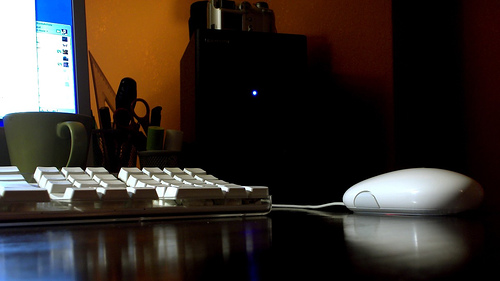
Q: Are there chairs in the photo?
A: No, there are no chairs.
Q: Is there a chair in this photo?
A: No, there are no chairs.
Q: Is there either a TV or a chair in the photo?
A: No, there are no chairs or televisions.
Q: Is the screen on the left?
A: Yes, the screen is on the left of the image.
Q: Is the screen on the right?
A: No, the screen is on the left of the image.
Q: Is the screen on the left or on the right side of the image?
A: The screen is on the left of the image.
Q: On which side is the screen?
A: The screen is on the left of the image.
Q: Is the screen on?
A: Yes, the screen is on.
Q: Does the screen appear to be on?
A: Yes, the screen is on.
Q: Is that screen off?
A: No, the screen is on.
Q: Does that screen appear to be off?
A: No, the screen is on.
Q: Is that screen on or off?
A: The screen is on.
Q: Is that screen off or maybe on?
A: The screen is on.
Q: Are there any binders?
A: No, there are no binders.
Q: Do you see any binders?
A: No, there are no binders.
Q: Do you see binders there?
A: No, there are no binders.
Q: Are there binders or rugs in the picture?
A: No, there are no binders or rugs.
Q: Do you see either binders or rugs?
A: No, there are no binders or rugs.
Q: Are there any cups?
A: Yes, there is a cup.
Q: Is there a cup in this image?
A: Yes, there is a cup.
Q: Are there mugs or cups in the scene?
A: Yes, there is a cup.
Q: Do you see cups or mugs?
A: Yes, there is a cup.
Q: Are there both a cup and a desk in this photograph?
A: Yes, there are both a cup and a desk.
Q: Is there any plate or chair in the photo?
A: No, there are no chairs or plates.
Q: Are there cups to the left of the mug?
A: No, the cup is to the right of the mug.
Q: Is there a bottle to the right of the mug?
A: No, there is a cup to the right of the mug.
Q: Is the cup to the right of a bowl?
A: No, the cup is to the right of the mug.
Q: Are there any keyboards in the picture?
A: Yes, there is a keyboard.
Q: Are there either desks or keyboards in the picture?
A: Yes, there is a keyboard.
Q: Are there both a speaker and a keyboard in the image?
A: No, there is a keyboard but no speakers.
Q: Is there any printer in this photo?
A: No, there are no printers.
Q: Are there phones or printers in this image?
A: No, there are no printers or phones.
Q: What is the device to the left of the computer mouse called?
A: The device is a keyboard.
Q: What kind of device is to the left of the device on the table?
A: The device is a keyboard.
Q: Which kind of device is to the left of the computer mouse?
A: The device is a keyboard.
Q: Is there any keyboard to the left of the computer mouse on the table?
A: Yes, there is a keyboard to the left of the mouse.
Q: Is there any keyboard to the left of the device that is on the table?
A: Yes, there is a keyboard to the left of the mouse.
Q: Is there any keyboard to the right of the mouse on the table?
A: No, the keyboard is to the left of the mouse.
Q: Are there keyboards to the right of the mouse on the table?
A: No, the keyboard is to the left of the mouse.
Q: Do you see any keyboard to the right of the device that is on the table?
A: No, the keyboard is to the left of the mouse.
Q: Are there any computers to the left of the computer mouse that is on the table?
A: No, there is a keyboard to the left of the mouse.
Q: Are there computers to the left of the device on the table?
A: No, there is a keyboard to the left of the mouse.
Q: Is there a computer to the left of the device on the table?
A: No, there is a keyboard to the left of the mouse.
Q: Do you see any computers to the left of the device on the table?
A: No, there is a keyboard to the left of the mouse.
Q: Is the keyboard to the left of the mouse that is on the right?
A: Yes, the keyboard is to the left of the mouse.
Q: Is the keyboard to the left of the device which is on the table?
A: Yes, the keyboard is to the left of the mouse.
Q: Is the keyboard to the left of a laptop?
A: No, the keyboard is to the left of the mouse.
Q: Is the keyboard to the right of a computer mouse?
A: No, the keyboard is to the left of a computer mouse.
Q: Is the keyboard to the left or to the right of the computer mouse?
A: The keyboard is to the left of the computer mouse.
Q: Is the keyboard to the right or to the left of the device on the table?
A: The keyboard is to the left of the computer mouse.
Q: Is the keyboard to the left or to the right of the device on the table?
A: The keyboard is to the left of the computer mouse.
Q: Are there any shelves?
A: No, there are no shelves.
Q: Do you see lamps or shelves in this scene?
A: No, there are no shelves or lamps.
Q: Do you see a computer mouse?
A: Yes, there is a computer mouse.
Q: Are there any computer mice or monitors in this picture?
A: Yes, there is a computer mouse.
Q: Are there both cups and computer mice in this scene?
A: Yes, there are both a computer mouse and a cup.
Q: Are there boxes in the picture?
A: No, there are no boxes.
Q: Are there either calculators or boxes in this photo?
A: No, there are no boxes or calculators.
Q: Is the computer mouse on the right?
A: Yes, the computer mouse is on the right of the image.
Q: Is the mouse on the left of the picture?
A: No, the mouse is on the right of the image.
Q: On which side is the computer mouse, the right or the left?
A: The computer mouse is on the right of the image.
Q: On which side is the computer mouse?
A: The computer mouse is on the right of the image.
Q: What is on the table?
A: The mouse is on the table.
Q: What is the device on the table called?
A: The device is a computer mouse.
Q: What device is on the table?
A: The device is a computer mouse.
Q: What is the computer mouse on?
A: The computer mouse is on the table.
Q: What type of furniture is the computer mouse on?
A: The computer mouse is on the table.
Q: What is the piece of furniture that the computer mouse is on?
A: The piece of furniture is a table.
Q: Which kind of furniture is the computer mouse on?
A: The computer mouse is on the table.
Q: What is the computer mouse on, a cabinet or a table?
A: The computer mouse is on a table.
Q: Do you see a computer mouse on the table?
A: Yes, there is a computer mouse on the table.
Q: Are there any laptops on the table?
A: No, there is a computer mouse on the table.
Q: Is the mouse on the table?
A: Yes, the mouse is on the table.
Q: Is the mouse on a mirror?
A: No, the mouse is on the table.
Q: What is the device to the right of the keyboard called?
A: The device is a computer mouse.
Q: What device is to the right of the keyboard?
A: The device is a computer mouse.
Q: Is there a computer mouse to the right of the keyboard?
A: Yes, there is a computer mouse to the right of the keyboard.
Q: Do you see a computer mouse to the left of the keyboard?
A: No, the computer mouse is to the right of the keyboard.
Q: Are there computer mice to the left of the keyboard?
A: No, the computer mouse is to the right of the keyboard.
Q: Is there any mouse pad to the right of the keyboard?
A: No, there is a computer mouse to the right of the keyboard.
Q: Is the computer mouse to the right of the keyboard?
A: Yes, the computer mouse is to the right of the keyboard.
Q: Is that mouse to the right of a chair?
A: No, the mouse is to the right of the keyboard.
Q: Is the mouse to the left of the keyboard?
A: No, the mouse is to the right of the keyboard.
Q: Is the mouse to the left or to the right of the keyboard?
A: The mouse is to the right of the keyboard.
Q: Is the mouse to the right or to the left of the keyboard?
A: The mouse is to the right of the keyboard.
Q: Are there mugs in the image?
A: Yes, there is a mug.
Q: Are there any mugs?
A: Yes, there is a mug.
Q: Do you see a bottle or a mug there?
A: Yes, there is a mug.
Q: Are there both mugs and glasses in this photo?
A: No, there is a mug but no glasses.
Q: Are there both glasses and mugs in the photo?
A: No, there is a mug but no glasses.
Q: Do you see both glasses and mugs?
A: No, there is a mug but no glasses.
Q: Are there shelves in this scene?
A: No, there are no shelves.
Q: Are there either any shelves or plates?
A: No, there are no shelves or plates.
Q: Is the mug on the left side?
A: Yes, the mug is on the left of the image.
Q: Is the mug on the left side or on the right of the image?
A: The mug is on the left of the image.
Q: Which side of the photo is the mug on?
A: The mug is on the left of the image.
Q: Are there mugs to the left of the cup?
A: Yes, there is a mug to the left of the cup.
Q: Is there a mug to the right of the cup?
A: No, the mug is to the left of the cup.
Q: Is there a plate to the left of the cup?
A: No, there is a mug to the left of the cup.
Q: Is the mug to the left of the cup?
A: Yes, the mug is to the left of the cup.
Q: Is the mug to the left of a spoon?
A: No, the mug is to the left of the cup.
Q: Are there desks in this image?
A: Yes, there is a desk.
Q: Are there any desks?
A: Yes, there is a desk.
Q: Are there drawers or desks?
A: Yes, there is a desk.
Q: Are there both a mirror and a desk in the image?
A: No, there is a desk but no mirrors.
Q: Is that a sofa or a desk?
A: That is a desk.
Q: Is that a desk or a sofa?
A: That is a desk.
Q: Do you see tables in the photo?
A: Yes, there is a table.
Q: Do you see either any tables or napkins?
A: Yes, there is a table.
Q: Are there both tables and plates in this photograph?
A: No, there is a table but no plates.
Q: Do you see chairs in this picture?
A: No, there are no chairs.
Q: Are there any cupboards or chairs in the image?
A: No, there are no chairs or cupboards.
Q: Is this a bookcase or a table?
A: This is a table.